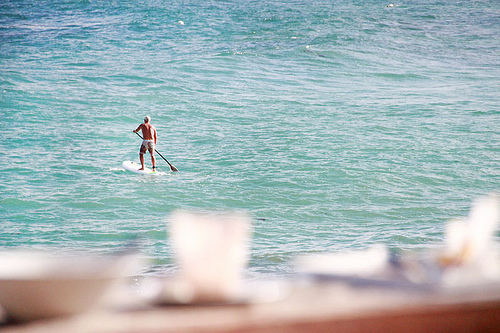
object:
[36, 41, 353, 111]
waves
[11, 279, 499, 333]
table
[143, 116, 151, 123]
hat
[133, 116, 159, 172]
man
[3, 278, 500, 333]
ledge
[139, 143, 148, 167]
legs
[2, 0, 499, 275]
ocean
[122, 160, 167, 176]
paddle board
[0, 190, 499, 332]
objects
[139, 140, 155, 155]
swim trunks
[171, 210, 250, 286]
cup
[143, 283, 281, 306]
saucer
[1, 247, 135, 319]
bowl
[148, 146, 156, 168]
leg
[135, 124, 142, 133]
arm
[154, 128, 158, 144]
arm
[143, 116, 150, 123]
head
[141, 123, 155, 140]
back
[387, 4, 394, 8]
ball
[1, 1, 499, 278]
water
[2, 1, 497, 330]
light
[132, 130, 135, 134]
hand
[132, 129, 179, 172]
oar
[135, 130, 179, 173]
paddle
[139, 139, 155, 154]
shorts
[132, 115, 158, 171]
body